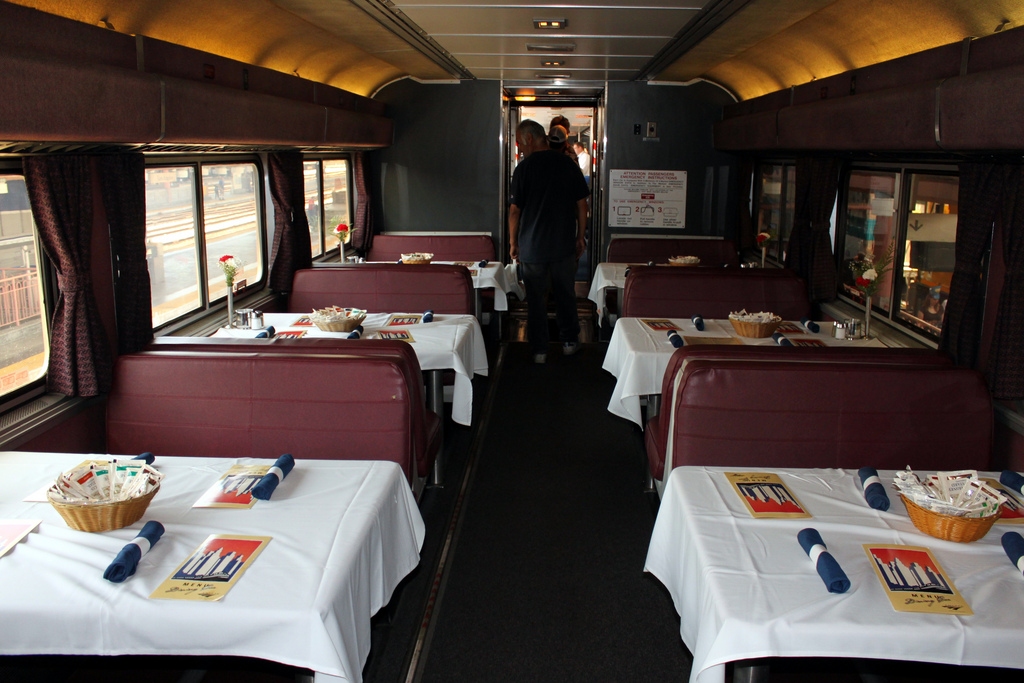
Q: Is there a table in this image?
A: Yes, there is a table.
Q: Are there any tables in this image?
A: Yes, there is a table.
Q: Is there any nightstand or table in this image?
A: Yes, there is a table.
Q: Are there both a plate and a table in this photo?
A: No, there is a table but no plates.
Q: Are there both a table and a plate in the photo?
A: No, there is a table but no plates.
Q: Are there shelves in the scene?
A: No, there are no shelves.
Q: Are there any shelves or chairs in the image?
A: No, there are no shelves or chairs.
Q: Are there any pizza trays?
A: No, there are no pizza trays.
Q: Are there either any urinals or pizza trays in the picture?
A: No, there are no pizza trays or urinals.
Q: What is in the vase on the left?
A: The flower is in the vase.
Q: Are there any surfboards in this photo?
A: No, there are no surfboards.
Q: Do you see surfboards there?
A: No, there are no surfboards.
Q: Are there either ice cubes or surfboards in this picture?
A: No, there are no surfboards or ice cubes.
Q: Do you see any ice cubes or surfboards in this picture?
A: No, there are no surfboards or ice cubes.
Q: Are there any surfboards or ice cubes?
A: No, there are no surfboards or ice cubes.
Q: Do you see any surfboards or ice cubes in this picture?
A: No, there are no surfboards or ice cubes.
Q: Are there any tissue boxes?
A: No, there are no tissue boxes.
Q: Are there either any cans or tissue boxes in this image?
A: No, there are no tissue boxes or cans.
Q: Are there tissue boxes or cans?
A: No, there are no tissue boxes or cans.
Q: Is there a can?
A: No, there are no cans.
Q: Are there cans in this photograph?
A: No, there are no cans.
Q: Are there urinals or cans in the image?
A: No, there are no cans or urinals.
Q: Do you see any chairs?
A: No, there are no chairs.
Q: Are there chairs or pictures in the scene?
A: No, there are no chairs or pictures.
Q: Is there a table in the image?
A: Yes, there is a table.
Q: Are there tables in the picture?
A: Yes, there is a table.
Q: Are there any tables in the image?
A: Yes, there is a table.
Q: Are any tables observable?
A: Yes, there is a table.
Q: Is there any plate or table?
A: Yes, there is a table.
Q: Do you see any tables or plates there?
A: Yes, there is a table.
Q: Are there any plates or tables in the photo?
A: Yes, there is a table.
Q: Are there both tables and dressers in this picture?
A: No, there is a table but no dressers.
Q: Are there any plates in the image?
A: No, there are no plates.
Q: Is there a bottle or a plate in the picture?
A: No, there are no plates or bottles.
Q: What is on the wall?
A: The sign is on the wall.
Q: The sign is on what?
A: The sign is on the wall.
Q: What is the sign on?
A: The sign is on the wall.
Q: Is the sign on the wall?
A: Yes, the sign is on the wall.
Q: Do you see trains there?
A: Yes, there is a train.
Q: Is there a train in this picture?
A: Yes, there is a train.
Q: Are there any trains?
A: Yes, there is a train.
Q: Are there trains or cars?
A: Yes, there is a train.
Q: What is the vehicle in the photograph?
A: The vehicle is a train.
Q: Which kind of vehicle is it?
A: The vehicle is a train.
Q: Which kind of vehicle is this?
A: This is a train.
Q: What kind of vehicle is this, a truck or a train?
A: This is a train.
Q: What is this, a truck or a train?
A: This is a train.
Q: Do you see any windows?
A: Yes, there is a window.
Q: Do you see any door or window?
A: Yes, there is a window.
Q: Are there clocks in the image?
A: No, there are no clocks.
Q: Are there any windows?
A: Yes, there is a window.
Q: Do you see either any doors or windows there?
A: Yes, there is a window.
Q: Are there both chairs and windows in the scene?
A: No, there is a window but no chairs.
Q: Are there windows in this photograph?
A: Yes, there is a window.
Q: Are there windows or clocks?
A: Yes, there is a window.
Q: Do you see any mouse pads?
A: No, there are no mouse pads.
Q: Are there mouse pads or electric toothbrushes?
A: No, there are no mouse pads or electric toothbrushes.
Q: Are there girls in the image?
A: No, there are no girls.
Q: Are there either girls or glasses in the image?
A: No, there are no girls or glasses.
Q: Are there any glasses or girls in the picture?
A: No, there are no girls or glasses.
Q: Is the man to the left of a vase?
A: No, the man is to the right of a vase.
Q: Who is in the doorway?
A: The man is in the doorway.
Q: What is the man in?
A: The man is in the doorway.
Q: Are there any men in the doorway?
A: Yes, there is a man in the doorway.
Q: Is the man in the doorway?
A: Yes, the man is in the doorway.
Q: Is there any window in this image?
A: Yes, there is a window.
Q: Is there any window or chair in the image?
A: Yes, there is a window.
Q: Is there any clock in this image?
A: No, there are no clocks.